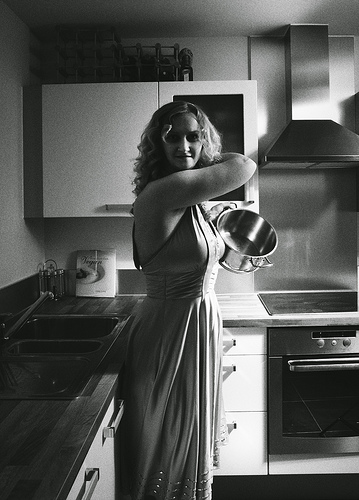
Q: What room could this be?
A: It is a kitchen.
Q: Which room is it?
A: It is a kitchen.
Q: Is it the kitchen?
A: Yes, it is the kitchen.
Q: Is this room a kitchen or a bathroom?
A: It is a kitchen.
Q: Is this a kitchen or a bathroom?
A: It is a kitchen.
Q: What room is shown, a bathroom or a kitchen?
A: It is a kitchen.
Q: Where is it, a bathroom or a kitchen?
A: It is a kitchen.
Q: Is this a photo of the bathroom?
A: No, the picture is showing the kitchen.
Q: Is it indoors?
A: Yes, it is indoors.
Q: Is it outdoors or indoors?
A: It is indoors.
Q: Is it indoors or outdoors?
A: It is indoors.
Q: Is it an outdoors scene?
A: No, it is indoors.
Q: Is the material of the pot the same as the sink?
A: Yes, both the pot and the sink are made of metal.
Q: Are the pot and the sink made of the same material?
A: Yes, both the pot and the sink are made of metal.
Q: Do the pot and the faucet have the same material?
A: Yes, both the pot and the faucet are made of metal.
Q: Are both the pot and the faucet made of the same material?
A: Yes, both the pot and the faucet are made of metal.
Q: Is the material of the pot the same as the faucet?
A: Yes, both the pot and the faucet are made of metal.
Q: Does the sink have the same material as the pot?
A: Yes, both the sink and the pot are made of metal.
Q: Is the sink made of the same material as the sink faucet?
A: Yes, both the sink and the faucet are made of metal.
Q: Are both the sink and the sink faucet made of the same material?
A: Yes, both the sink and the faucet are made of metal.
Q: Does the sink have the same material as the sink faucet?
A: Yes, both the sink and the faucet are made of metal.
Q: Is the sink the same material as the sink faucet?
A: Yes, both the sink and the faucet are made of metal.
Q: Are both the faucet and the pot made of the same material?
A: Yes, both the faucet and the pot are made of metal.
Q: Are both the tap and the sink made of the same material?
A: Yes, both the tap and the sink are made of metal.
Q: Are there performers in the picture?
A: No, there are no performers.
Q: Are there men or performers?
A: No, there are no performers or men.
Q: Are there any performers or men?
A: No, there are no performers or men.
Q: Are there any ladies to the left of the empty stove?
A: Yes, there is a lady to the left of the stove.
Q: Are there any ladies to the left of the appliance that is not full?
A: Yes, there is a lady to the left of the stove.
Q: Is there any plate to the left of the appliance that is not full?
A: No, there is a lady to the left of the stove.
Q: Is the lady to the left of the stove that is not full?
A: Yes, the lady is to the left of the stove.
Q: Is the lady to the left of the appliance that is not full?
A: Yes, the lady is to the left of the stove.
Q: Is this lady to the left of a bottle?
A: No, the lady is to the left of the stove.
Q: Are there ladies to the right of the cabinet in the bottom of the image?
A: Yes, there is a lady to the right of the cabinet.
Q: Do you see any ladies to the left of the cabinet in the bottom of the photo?
A: No, the lady is to the right of the cabinet.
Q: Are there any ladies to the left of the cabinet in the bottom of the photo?
A: No, the lady is to the right of the cabinet.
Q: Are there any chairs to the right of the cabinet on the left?
A: No, there is a lady to the right of the cabinet.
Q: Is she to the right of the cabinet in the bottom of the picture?
A: Yes, the lady is to the right of the cabinet.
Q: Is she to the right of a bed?
A: No, the lady is to the right of the cabinet.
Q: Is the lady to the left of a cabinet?
A: No, the lady is to the right of a cabinet.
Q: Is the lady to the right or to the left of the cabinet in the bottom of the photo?
A: The lady is to the right of the cabinet.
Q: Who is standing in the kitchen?
A: The lady is standing in the kitchen.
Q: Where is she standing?
A: The lady is standing in the kitchen.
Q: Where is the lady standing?
A: The lady is standing in the kitchen.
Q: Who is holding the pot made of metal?
A: The lady is holding the pot.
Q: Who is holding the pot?
A: The lady is holding the pot.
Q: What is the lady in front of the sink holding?
A: The lady is holding the pot.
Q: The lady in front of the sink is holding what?
A: The lady is holding the pot.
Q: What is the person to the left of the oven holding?
A: The lady is holding the pot.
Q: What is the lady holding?
A: The lady is holding the pot.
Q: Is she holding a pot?
A: Yes, the lady is holding a pot.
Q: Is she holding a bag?
A: No, the lady is holding a pot.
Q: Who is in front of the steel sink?
A: The lady is in front of the sink.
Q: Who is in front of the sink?
A: The lady is in front of the sink.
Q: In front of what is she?
A: The lady is in front of the sink.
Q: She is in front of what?
A: The lady is in front of the sink.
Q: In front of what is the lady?
A: The lady is in front of the sink.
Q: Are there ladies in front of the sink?
A: Yes, there is a lady in front of the sink.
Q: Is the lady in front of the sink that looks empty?
A: Yes, the lady is in front of the sink.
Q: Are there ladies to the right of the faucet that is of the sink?
A: Yes, there is a lady to the right of the faucet.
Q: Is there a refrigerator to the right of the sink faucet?
A: No, there is a lady to the right of the faucet.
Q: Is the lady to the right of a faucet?
A: Yes, the lady is to the right of a faucet.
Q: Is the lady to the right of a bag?
A: No, the lady is to the right of a faucet.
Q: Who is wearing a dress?
A: The lady is wearing a dress.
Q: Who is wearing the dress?
A: The lady is wearing a dress.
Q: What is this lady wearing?
A: The lady is wearing a dress.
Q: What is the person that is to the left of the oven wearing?
A: The lady is wearing a dress.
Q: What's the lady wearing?
A: The lady is wearing a dress.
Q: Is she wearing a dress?
A: Yes, the lady is wearing a dress.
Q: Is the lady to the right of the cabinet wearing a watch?
A: No, the lady is wearing a dress.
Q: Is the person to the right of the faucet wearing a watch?
A: No, the lady is wearing a dress.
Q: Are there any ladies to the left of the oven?
A: Yes, there is a lady to the left of the oven.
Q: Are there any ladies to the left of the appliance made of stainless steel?
A: Yes, there is a lady to the left of the oven.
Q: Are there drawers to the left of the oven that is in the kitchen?
A: No, there is a lady to the left of the oven.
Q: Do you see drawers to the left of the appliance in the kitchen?
A: No, there is a lady to the left of the oven.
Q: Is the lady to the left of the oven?
A: Yes, the lady is to the left of the oven.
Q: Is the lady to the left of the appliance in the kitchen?
A: Yes, the lady is to the left of the oven.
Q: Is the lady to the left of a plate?
A: No, the lady is to the left of the oven.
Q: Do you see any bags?
A: No, there are no bags.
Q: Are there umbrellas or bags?
A: No, there are no bags or umbrellas.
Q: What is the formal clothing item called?
A: The clothing item is a dress.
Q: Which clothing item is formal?
A: The clothing item is a dress.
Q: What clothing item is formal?
A: The clothing item is a dress.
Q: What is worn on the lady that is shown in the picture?
A: The dress is worn on the lady.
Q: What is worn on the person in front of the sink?
A: The dress is worn on the lady.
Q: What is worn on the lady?
A: The dress is worn on the lady.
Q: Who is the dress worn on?
A: The dress is worn on the lady.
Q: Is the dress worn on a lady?
A: Yes, the dress is worn on a lady.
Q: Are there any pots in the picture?
A: Yes, there is a pot.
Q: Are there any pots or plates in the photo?
A: Yes, there is a pot.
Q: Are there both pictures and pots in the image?
A: No, there is a pot but no pictures.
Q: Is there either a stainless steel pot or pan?
A: Yes, there is a stainless steel pot.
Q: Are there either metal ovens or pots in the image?
A: Yes, there is a metal pot.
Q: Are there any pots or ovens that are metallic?
A: Yes, the pot is metallic.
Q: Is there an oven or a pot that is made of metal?
A: Yes, the pot is made of metal.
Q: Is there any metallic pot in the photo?
A: Yes, there is a metal pot.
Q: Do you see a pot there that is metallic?
A: Yes, there is a pot that is metallic.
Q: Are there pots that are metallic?
A: Yes, there is a pot that is metallic.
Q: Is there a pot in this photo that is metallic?
A: Yes, there is a pot that is metallic.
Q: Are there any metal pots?
A: Yes, there is a pot that is made of metal.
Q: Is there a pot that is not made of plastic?
A: Yes, there is a pot that is made of metal.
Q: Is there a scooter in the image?
A: No, there are no scooters.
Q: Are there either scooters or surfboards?
A: No, there are no scooters or surfboards.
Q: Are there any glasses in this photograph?
A: No, there are no glasses.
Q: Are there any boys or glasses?
A: No, there are no glasses or boys.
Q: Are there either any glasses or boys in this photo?
A: No, there are no glasses or boys.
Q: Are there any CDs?
A: No, there are no cds.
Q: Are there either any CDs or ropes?
A: No, there are no CDs or ropes.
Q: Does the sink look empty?
A: Yes, the sink is empty.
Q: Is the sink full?
A: No, the sink is empty.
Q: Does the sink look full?
A: No, the sink is empty.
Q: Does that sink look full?
A: No, the sink is empty.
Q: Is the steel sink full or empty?
A: The sink is empty.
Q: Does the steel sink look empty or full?
A: The sink is empty.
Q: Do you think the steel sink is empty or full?
A: The sink is empty.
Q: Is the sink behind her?
A: Yes, the sink is behind a lady.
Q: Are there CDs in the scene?
A: No, there are no cds.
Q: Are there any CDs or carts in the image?
A: No, there are no CDs or carts.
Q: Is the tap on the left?
A: Yes, the tap is on the left of the image.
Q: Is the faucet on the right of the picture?
A: No, the faucet is on the left of the image.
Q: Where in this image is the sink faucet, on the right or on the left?
A: The tap is on the left of the image.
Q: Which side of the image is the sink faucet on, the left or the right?
A: The tap is on the left of the image.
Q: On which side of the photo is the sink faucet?
A: The faucet is on the left of the image.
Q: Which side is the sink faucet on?
A: The faucet is on the left of the image.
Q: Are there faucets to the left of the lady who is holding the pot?
A: Yes, there is a faucet to the left of the lady.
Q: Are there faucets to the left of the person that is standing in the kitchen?
A: Yes, there is a faucet to the left of the lady.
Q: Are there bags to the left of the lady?
A: No, there is a faucet to the left of the lady.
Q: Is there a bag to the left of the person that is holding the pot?
A: No, there is a faucet to the left of the lady.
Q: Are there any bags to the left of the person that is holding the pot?
A: No, there is a faucet to the left of the lady.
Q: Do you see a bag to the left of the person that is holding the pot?
A: No, there is a faucet to the left of the lady.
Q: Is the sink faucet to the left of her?
A: Yes, the tap is to the left of a lady.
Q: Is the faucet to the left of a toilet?
A: No, the faucet is to the left of a lady.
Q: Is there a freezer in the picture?
A: No, there are no refrigerators.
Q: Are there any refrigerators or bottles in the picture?
A: No, there are no refrigerators or bottles.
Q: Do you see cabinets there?
A: Yes, there is a cabinet.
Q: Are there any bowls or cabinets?
A: Yes, there is a cabinet.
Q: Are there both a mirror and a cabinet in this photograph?
A: No, there is a cabinet but no mirrors.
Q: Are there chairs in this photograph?
A: No, there are no chairs.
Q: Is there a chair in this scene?
A: No, there are no chairs.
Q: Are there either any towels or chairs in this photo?
A: No, there are no chairs or towels.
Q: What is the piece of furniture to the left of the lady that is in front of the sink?
A: The piece of furniture is a cabinet.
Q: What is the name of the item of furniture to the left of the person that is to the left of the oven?
A: The piece of furniture is a cabinet.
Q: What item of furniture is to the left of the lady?
A: The piece of furniture is a cabinet.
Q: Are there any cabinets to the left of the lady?
A: Yes, there is a cabinet to the left of the lady.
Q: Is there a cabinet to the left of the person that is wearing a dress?
A: Yes, there is a cabinet to the left of the lady.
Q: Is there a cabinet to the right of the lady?
A: No, the cabinet is to the left of the lady.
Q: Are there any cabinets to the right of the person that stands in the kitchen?
A: No, the cabinet is to the left of the lady.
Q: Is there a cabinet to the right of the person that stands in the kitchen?
A: No, the cabinet is to the left of the lady.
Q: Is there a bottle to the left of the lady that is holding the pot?
A: No, there is a cabinet to the left of the lady.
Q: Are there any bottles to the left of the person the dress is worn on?
A: No, there is a cabinet to the left of the lady.